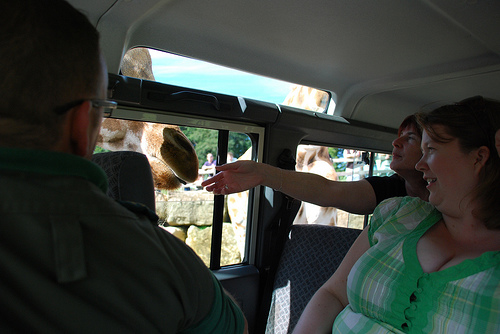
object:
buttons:
[415, 287, 424, 296]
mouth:
[153, 147, 191, 189]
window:
[120, 47, 339, 115]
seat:
[264, 221, 362, 333]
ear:
[472, 145, 493, 175]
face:
[414, 122, 491, 208]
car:
[4, 2, 500, 334]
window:
[290, 144, 376, 232]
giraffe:
[93, 47, 200, 191]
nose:
[163, 129, 198, 157]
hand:
[200, 157, 264, 196]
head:
[95, 49, 198, 198]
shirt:
[332, 193, 499, 333]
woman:
[285, 95, 496, 334]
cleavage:
[413, 244, 476, 275]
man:
[2, 3, 253, 333]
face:
[85, 48, 107, 154]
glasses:
[63, 96, 118, 119]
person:
[199, 114, 429, 214]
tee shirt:
[362, 174, 407, 205]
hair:
[0, 2, 107, 160]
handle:
[106, 71, 281, 130]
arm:
[256, 163, 402, 215]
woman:
[200, 114, 430, 216]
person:
[202, 152, 218, 171]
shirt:
[200, 162, 216, 170]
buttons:
[420, 269, 430, 281]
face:
[416, 119, 475, 209]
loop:
[47, 212, 90, 284]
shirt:
[2, 137, 250, 333]